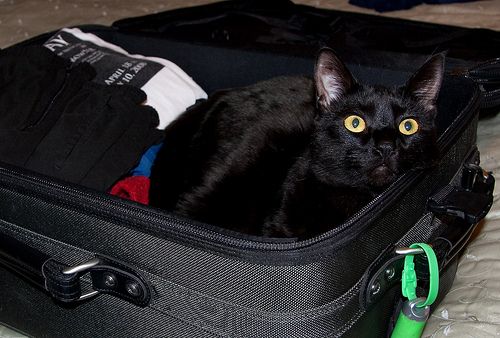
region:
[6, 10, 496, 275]
Black cat in a suitcase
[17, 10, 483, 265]
Black cat staring in black suitcase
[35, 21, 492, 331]
Black cat with eyes wide open in black suitcase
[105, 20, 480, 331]
Black cat sitting next to rolled socks in black suitcase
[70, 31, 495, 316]
Black cat next to clothes staring in a suitcase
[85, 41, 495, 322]
Black cat sitting and looking in suitcase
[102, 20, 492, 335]
Black cat sits on top of clothes in open suitcase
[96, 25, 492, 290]
Black cat sits on top of clothes and stares inside of suitcase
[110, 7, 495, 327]
Black cat opens eyes wide inside of suitcase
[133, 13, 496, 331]
Black cat is staring in straight ahead next to clothes in suitcase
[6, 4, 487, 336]
a black cat in a suitcase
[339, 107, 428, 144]
eyes of cat are round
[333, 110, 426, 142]
eyes of cat are orange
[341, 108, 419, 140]
pupiles of cat are black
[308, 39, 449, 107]
pointy ears of cat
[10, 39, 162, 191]
a pair of gloves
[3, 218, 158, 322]
a handle of suitcase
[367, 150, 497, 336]
a handle of suitcase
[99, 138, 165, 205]
blue and red clothes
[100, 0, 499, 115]
lid of a suitcase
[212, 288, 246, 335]
edge of a bag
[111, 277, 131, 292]
part of an handle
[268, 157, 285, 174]
body of a cat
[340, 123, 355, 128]
part of an eye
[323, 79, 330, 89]
ear of a cat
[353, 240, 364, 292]
side of a bag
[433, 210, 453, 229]
edge of a bag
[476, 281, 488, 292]
part of a mattress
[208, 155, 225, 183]
edge of a cat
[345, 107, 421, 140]
yellow eyes on a cat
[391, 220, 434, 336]
bright green luggage tag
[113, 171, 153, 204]
red folded clothing in a suit case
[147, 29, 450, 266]
black cat in a suit case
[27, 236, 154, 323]
black handle on a suit case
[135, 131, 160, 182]
blue fabric on a suit case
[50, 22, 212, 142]
white folded shirt with black motif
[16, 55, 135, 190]
folded black clothing in a suit case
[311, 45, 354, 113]
ear on a black cat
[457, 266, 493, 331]
beige bed spread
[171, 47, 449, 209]
A cat in a suitcase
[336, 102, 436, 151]
The cat has yellow eyes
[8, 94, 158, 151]
Black pants in the suitcase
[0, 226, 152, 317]
The handle on the suitcase is plastic and metal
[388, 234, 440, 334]
The luggage tag is green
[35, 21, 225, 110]
White clothing that is brand new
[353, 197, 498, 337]
The suitcase is laying on the bed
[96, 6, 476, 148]
The suitcase is open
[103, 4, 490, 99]
this is the lid of the suitcase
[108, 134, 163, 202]
Red and blue apparel in the suitcase